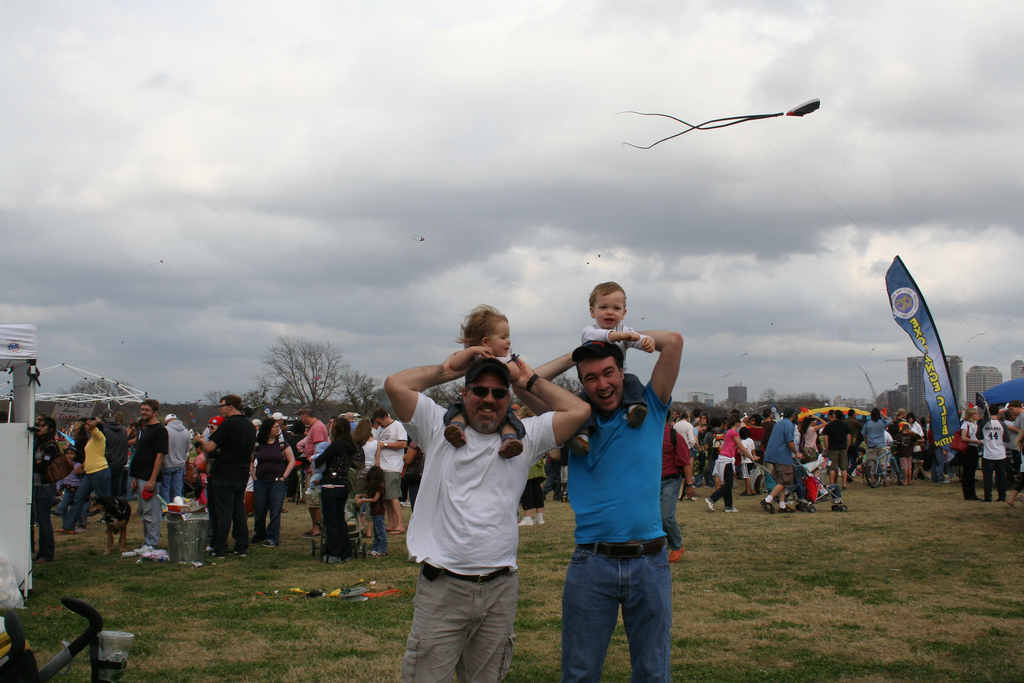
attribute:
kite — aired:
[590, 68, 970, 199]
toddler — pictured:
[575, 296, 750, 418]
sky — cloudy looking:
[104, 85, 817, 336]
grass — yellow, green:
[178, 524, 1017, 652]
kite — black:
[619, 106, 1011, 170]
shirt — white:
[385, 381, 613, 609]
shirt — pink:
[687, 413, 839, 541]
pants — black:
[687, 413, 839, 541]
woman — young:
[25, 425, 112, 547]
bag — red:
[918, 384, 1017, 530]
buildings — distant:
[698, 349, 1016, 422]